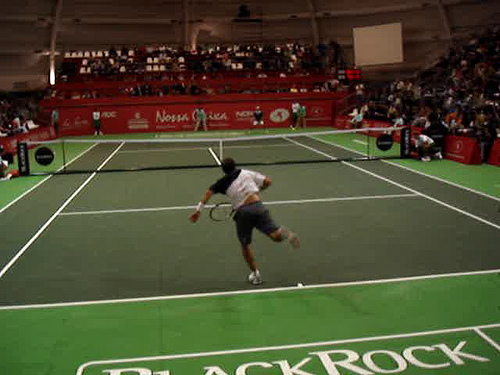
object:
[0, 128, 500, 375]
court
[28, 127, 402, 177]
net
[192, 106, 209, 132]
people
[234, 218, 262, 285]
leg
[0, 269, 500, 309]
lines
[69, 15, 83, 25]
lights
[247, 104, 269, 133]
player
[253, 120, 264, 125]
shorts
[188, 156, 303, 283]
player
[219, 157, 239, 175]
head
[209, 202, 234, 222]
racket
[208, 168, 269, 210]
shirt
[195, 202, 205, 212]
wristband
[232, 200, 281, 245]
shorts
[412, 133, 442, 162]
ballboy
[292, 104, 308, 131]
linesman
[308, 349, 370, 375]
r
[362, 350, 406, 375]
o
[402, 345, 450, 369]
c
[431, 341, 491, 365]
k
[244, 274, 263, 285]
shoes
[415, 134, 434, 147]
shirt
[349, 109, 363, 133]
man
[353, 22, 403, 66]
screen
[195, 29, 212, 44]
shadow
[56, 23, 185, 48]
wall